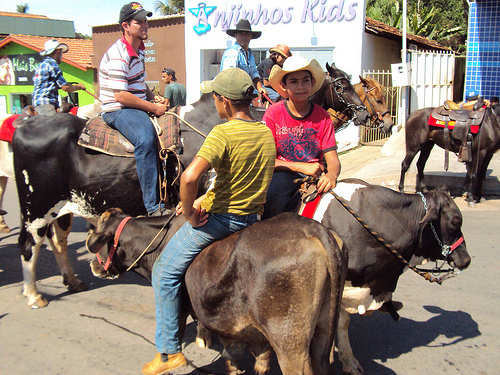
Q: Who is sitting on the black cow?
A: A little boy.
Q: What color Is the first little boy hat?
A: Green.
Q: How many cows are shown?
A: Three.